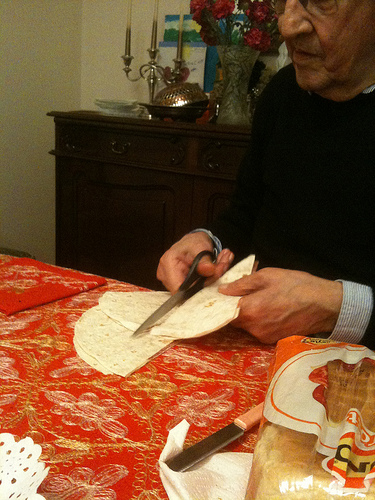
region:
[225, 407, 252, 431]
brown wooden handle on knife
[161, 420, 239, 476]
silver blade on knife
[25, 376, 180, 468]
gold and red design on table cloth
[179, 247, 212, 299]
black handle on scissors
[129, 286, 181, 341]
silver blade on scissors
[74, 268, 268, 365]
man cutting white tortillas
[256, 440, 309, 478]
white bread in packet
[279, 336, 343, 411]
orange and white bread bag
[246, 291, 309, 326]
purple veins in man's hand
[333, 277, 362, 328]
edge of blue and white shirt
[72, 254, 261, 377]
Tortillas being cut with scissors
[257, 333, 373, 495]
A loaf of bread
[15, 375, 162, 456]
Gold pattern on a red tablecloth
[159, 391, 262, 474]
A small wooden handled knife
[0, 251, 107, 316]
A red napkin with old design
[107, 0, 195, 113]
A silver candleabra with room for three candles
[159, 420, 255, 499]
A white two ply paper towel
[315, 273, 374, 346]
Cuff of a striped man's dress shirt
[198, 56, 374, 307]
A man's black sweater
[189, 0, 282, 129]
A clear vase with red flowers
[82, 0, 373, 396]
A man using scissors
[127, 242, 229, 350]
A pair of scissors being used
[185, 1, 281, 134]
A vase with red flowers in it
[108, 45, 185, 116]
A silver candlestick holder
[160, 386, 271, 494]
A knife with a plastic handle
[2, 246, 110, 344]
A red embroidered napkin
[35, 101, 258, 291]
A piece of wooden furniture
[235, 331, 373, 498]
A loaf of bread in a plastic wrapper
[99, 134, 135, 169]
A metal drawer handle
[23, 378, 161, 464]
An embroidered design on a tablecloth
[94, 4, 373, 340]
man holding scissors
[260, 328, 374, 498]
loaf of bread on table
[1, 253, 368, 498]
red tablecloth with white and gold stitching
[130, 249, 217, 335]
scissors with blach handles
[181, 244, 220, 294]
black handles of scissors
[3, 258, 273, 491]
white and gold stitching on table cloth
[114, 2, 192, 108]
candlestick with three candles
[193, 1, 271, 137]
clear vase with flowers in it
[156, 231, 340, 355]
hands of man using scissors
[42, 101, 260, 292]
dark brown furniture behind man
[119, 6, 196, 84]
candleabra on chest sitting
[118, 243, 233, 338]
scissors cutting a tortilla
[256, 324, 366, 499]
bread on the table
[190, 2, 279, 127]
vase full of flowers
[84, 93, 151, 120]
white dish sitting on desk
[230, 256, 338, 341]
man's right hand on table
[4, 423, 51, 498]
doilly on table cloth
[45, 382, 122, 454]
red with gold tablecloth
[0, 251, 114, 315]
napkin on the table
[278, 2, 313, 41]
man's nose on his face